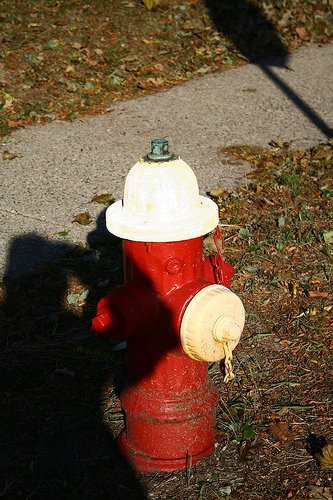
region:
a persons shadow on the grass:
[0, 231, 180, 498]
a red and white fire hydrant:
[90, 135, 246, 473]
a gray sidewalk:
[0, 41, 331, 285]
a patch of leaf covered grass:
[1, 0, 332, 138]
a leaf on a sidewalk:
[71, 210, 91, 224]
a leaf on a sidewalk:
[87, 192, 113, 202]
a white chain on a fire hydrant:
[223, 340, 234, 381]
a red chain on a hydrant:
[210, 224, 223, 284]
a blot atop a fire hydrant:
[146, 139, 174, 159]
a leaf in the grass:
[269, 421, 295, 442]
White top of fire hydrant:
[102, 157, 221, 246]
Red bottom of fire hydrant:
[85, 234, 235, 476]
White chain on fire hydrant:
[213, 341, 242, 385]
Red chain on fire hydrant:
[206, 223, 227, 288]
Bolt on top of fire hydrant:
[142, 136, 176, 164]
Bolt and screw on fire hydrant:
[139, 240, 158, 256]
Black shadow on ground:
[195, 0, 332, 148]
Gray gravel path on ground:
[0, 37, 332, 285]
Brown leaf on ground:
[258, 412, 310, 449]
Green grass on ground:
[217, 387, 280, 449]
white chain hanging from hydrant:
[186, 322, 255, 378]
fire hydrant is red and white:
[122, 162, 229, 446]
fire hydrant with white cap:
[125, 144, 209, 237]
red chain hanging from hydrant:
[209, 237, 221, 281]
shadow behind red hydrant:
[66, 438, 98, 475]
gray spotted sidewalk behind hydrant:
[193, 102, 219, 110]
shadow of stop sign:
[236, 6, 302, 110]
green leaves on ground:
[97, 59, 131, 92]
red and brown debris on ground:
[78, 90, 136, 119]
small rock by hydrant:
[218, 479, 232, 493]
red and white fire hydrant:
[87, 137, 244, 467]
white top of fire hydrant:
[107, 153, 216, 234]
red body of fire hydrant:
[91, 241, 233, 470]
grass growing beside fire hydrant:
[220, 359, 304, 447]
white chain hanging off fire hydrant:
[220, 344, 239, 384]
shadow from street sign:
[209, 2, 332, 147]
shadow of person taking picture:
[5, 232, 145, 494]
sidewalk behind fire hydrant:
[8, 64, 332, 268]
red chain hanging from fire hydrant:
[213, 231, 231, 290]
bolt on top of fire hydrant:
[148, 136, 174, 158]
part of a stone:
[221, 480, 240, 494]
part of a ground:
[255, 465, 265, 474]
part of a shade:
[80, 410, 103, 439]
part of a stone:
[222, 483, 233, 492]